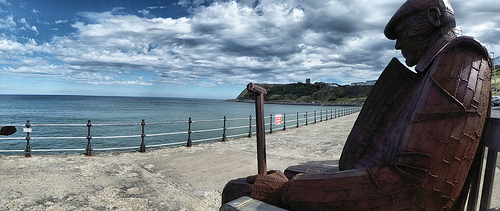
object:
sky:
[0, 0, 499, 99]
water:
[0, 94, 362, 153]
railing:
[1, 106, 365, 158]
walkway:
[1, 109, 363, 211]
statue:
[219, 0, 500, 211]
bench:
[0, 109, 499, 210]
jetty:
[226, 99, 367, 107]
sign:
[273, 113, 281, 126]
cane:
[246, 81, 267, 175]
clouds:
[0, 1, 499, 87]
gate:
[0, 104, 364, 159]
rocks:
[223, 82, 376, 106]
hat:
[383, 0, 456, 40]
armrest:
[220, 195, 293, 210]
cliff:
[226, 78, 378, 108]